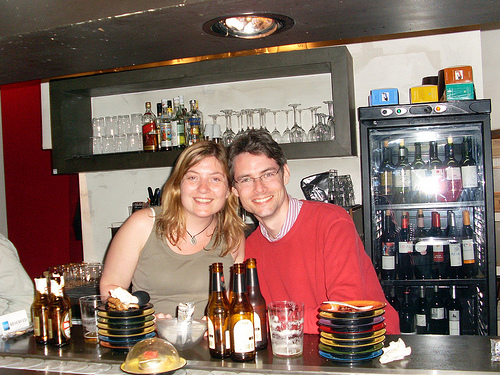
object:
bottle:
[33, 270, 52, 347]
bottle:
[203, 260, 231, 359]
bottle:
[243, 257, 270, 348]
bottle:
[227, 262, 257, 362]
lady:
[98, 139, 243, 336]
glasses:
[232, 166, 283, 187]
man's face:
[227, 133, 290, 217]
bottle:
[51, 270, 73, 348]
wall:
[403, 108, 445, 151]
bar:
[2, 291, 498, 373]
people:
[85, 109, 440, 353]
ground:
[418, 101, 452, 141]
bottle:
[444, 211, 464, 275]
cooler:
[357, 105, 498, 334]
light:
[213, 12, 282, 43]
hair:
[148, 140, 253, 260]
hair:
[221, 127, 288, 174]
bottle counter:
[195, 250, 270, 367]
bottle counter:
[30, 268, 82, 353]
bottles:
[458, 140, 485, 198]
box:
[367, 84, 401, 106]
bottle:
[377, 212, 394, 272]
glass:
[266, 301, 302, 355]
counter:
[2, 331, 498, 373]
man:
[225, 132, 400, 334]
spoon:
[322, 295, 380, 311]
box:
[408, 84, 439, 104]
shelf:
[42, 46, 363, 172]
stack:
[314, 300, 386, 364]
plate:
[316, 296, 386, 316]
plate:
[317, 310, 385, 321]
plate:
[316, 318, 385, 329]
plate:
[316, 324, 386, 335]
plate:
[317, 337, 387, 350]